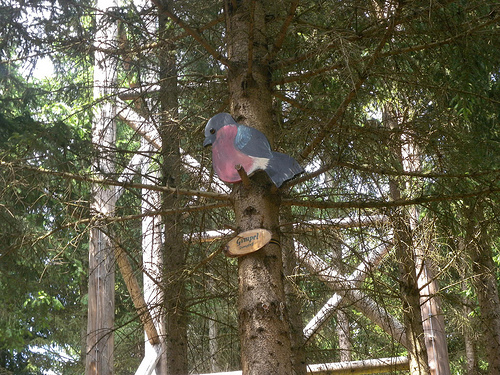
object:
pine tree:
[112, 0, 397, 372]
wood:
[237, 200, 276, 221]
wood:
[234, 231, 263, 252]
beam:
[84, 4, 123, 373]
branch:
[231, 160, 255, 195]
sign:
[221, 228, 274, 257]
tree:
[3, 2, 98, 372]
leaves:
[0, 239, 21, 259]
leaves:
[27, 296, 67, 327]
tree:
[1, 182, 142, 372]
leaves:
[155, 50, 184, 75]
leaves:
[452, 50, 484, 82]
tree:
[377, 7, 481, 370]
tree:
[268, 6, 468, 373]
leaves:
[385, 269, 410, 296]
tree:
[218, 0, 310, 371]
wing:
[229, 123, 272, 157]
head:
[200, 110, 240, 150]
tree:
[192, 16, 322, 344]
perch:
[233, 166, 251, 190]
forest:
[45, 38, 473, 351]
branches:
[31, 134, 160, 188]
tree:
[191, 68, 302, 349]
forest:
[23, 43, 480, 364]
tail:
[266, 150, 300, 188]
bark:
[254, 301, 269, 314]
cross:
[296, 238, 407, 344]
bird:
[203, 112, 300, 186]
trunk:
[214, 127, 292, 263]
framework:
[89, 60, 449, 337]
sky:
[15, 10, 59, 87]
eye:
[207, 127, 215, 134]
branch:
[78, 199, 200, 220]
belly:
[208, 139, 256, 183]